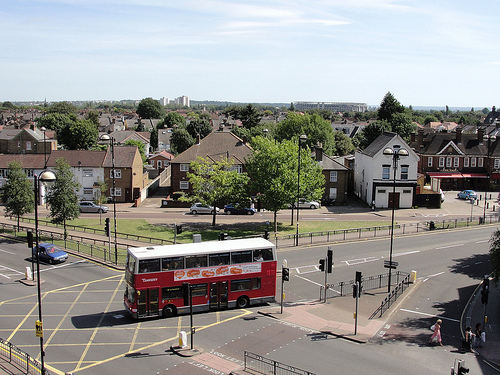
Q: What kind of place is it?
A: It is a street.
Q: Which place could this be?
A: It is a street.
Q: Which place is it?
A: It is a street.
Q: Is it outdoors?
A: Yes, it is outdoors.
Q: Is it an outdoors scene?
A: Yes, it is outdoors.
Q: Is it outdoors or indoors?
A: It is outdoors.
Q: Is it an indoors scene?
A: No, it is outdoors.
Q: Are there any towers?
A: No, there are no towers.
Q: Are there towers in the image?
A: No, there are no towers.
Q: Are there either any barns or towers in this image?
A: No, there are no towers or barns.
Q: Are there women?
A: Yes, there is a woman.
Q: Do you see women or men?
A: Yes, there is a woman.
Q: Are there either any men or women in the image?
A: Yes, there is a woman.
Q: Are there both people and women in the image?
A: Yes, there are both a woman and people.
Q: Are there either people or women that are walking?
A: Yes, the woman is walking.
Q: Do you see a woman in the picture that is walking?
A: Yes, there is a woman that is walking.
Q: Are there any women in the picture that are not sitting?
A: Yes, there is a woman that is walking.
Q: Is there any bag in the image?
A: No, there are no bags.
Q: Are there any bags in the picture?
A: No, there are no bags.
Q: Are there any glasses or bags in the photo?
A: No, there are no bags or glasses.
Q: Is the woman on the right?
A: Yes, the woman is on the right of the image.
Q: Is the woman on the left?
A: No, the woman is on the right of the image.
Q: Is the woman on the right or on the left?
A: The woman is on the right of the image.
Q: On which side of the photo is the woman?
A: The woman is on the right of the image.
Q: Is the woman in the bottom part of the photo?
A: Yes, the woman is in the bottom of the image.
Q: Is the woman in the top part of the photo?
A: No, the woman is in the bottom of the image.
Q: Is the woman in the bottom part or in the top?
A: The woman is in the bottom of the image.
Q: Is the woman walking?
A: Yes, the woman is walking.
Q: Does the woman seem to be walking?
A: Yes, the woman is walking.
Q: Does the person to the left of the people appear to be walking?
A: Yes, the woman is walking.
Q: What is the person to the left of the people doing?
A: The woman is walking.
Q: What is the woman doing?
A: The woman is walking.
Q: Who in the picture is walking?
A: The woman is walking.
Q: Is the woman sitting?
A: No, the woman is walking.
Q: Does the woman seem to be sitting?
A: No, the woman is walking.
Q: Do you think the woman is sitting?
A: No, the woman is walking.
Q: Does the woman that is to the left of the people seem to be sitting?
A: No, the woman is walking.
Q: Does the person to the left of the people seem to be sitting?
A: No, the woman is walking.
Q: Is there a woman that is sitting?
A: No, there is a woman but she is walking.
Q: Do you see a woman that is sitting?
A: No, there is a woman but she is walking.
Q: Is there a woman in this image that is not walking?
A: No, there is a woman but she is walking.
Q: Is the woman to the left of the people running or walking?
A: The woman is walking.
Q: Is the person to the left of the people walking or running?
A: The woman is walking.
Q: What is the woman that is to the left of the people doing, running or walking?
A: The woman is walking.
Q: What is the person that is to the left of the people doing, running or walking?
A: The woman is walking.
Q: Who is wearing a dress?
A: The woman is wearing a dress.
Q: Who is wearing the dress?
A: The woman is wearing a dress.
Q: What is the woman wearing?
A: The woman is wearing a dress.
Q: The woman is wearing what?
A: The woman is wearing a dress.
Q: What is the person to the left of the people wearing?
A: The woman is wearing a dress.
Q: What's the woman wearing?
A: The woman is wearing a dress.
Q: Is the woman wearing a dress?
A: Yes, the woman is wearing a dress.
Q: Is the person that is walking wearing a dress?
A: Yes, the woman is wearing a dress.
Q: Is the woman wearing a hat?
A: No, the woman is wearing a dress.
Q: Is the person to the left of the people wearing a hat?
A: No, the woman is wearing a dress.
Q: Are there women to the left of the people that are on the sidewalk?
A: Yes, there is a woman to the left of the people.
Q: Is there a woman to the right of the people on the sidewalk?
A: No, the woman is to the left of the people.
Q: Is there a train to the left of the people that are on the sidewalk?
A: No, there is a woman to the left of the people.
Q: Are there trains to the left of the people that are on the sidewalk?
A: No, there is a woman to the left of the people.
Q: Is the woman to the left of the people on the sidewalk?
A: Yes, the woman is to the left of the people.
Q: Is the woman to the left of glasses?
A: No, the woman is to the left of the people.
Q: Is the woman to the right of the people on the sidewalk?
A: No, the woman is to the left of the people.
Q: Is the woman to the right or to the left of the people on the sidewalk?
A: The woman is to the left of the people.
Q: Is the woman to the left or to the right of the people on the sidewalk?
A: The woman is to the left of the people.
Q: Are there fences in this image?
A: Yes, there is a fence.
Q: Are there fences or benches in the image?
A: Yes, there is a fence.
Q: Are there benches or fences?
A: Yes, there is a fence.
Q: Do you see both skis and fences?
A: No, there is a fence but no skis.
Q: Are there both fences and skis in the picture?
A: No, there is a fence but no skis.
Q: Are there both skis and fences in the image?
A: No, there is a fence but no skis.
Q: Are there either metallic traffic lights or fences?
A: Yes, there is a metal fence.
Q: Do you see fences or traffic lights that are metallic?
A: Yes, the fence is metallic.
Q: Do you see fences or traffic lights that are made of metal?
A: Yes, the fence is made of metal.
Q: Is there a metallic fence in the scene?
A: Yes, there is a metal fence.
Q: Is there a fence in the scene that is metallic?
A: Yes, there is a fence that is metallic.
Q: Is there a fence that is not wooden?
A: Yes, there is a metallic fence.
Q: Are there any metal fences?
A: Yes, there is a fence that is made of metal.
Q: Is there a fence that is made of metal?
A: Yes, there is a fence that is made of metal.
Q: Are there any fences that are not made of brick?
A: Yes, there is a fence that is made of metal.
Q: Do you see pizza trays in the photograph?
A: No, there are no pizza trays.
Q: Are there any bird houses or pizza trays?
A: No, there are no pizza trays or bird houses.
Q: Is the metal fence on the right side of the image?
A: Yes, the fence is on the right of the image.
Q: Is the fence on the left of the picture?
A: No, the fence is on the right of the image.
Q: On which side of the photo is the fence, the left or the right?
A: The fence is on the right of the image.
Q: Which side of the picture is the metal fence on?
A: The fence is on the right of the image.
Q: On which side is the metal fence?
A: The fence is on the right of the image.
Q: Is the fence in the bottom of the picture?
A: Yes, the fence is in the bottom of the image.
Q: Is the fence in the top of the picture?
A: No, the fence is in the bottom of the image.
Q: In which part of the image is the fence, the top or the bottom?
A: The fence is in the bottom of the image.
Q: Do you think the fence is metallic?
A: Yes, the fence is metallic.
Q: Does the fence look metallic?
A: Yes, the fence is metallic.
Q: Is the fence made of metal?
A: Yes, the fence is made of metal.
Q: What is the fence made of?
A: The fence is made of metal.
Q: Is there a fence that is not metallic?
A: No, there is a fence but it is metallic.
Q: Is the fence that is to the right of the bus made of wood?
A: No, the fence is made of metal.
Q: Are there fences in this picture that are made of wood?
A: No, there is a fence but it is made of metal.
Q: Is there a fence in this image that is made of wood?
A: No, there is a fence but it is made of metal.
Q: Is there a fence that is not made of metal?
A: No, there is a fence but it is made of metal.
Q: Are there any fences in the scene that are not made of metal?
A: No, there is a fence but it is made of metal.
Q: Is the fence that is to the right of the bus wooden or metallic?
A: The fence is metallic.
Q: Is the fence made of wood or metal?
A: The fence is made of metal.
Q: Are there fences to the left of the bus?
A: No, the fence is to the right of the bus.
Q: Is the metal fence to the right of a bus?
A: Yes, the fence is to the right of a bus.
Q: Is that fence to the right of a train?
A: No, the fence is to the right of a bus.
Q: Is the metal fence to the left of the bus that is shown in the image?
A: No, the fence is to the right of the bus.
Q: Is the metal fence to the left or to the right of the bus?
A: The fence is to the right of the bus.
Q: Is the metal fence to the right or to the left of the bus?
A: The fence is to the right of the bus.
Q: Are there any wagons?
A: No, there are no wagons.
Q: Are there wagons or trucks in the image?
A: No, there are no wagons or trucks.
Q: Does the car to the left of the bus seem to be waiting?
A: Yes, the car is waiting.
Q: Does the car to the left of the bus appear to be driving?
A: No, the car is waiting.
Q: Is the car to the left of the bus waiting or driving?
A: The car is waiting.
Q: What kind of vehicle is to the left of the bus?
A: The vehicle is a car.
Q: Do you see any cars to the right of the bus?
A: No, the car is to the left of the bus.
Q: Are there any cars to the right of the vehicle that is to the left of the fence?
A: No, the car is to the left of the bus.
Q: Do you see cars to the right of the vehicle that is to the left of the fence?
A: No, the car is to the left of the bus.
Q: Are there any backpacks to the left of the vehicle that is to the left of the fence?
A: No, there is a car to the left of the bus.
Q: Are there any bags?
A: No, there are no bags.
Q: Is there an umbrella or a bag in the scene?
A: No, there are no bags or umbrellas.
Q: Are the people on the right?
A: Yes, the people are on the right of the image.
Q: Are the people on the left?
A: No, the people are on the right of the image.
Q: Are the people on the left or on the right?
A: The people are on the right of the image.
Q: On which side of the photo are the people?
A: The people are on the right of the image.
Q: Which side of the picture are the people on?
A: The people are on the right of the image.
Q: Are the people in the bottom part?
A: Yes, the people are in the bottom of the image.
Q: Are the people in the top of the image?
A: No, the people are in the bottom of the image.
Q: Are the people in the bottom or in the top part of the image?
A: The people are in the bottom of the image.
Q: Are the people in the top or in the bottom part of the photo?
A: The people are in the bottom of the image.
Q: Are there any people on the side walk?
A: Yes, there are people on the side walk.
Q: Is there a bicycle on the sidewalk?
A: No, there are people on the sidewalk.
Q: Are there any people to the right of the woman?
A: Yes, there are people to the right of the woman.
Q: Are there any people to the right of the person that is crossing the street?
A: Yes, there are people to the right of the woman.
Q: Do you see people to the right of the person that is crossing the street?
A: Yes, there are people to the right of the woman.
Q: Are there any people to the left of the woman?
A: No, the people are to the right of the woman.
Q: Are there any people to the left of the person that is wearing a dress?
A: No, the people are to the right of the woman.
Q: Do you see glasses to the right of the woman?
A: No, there are people to the right of the woman.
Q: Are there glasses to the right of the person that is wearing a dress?
A: No, there are people to the right of the woman.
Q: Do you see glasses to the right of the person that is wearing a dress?
A: No, there are people to the right of the woman.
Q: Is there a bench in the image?
A: No, there are no benches.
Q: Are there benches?
A: No, there are no benches.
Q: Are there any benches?
A: No, there are no benches.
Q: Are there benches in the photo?
A: No, there are no benches.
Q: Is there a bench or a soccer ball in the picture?
A: No, there are no benches or soccer balls.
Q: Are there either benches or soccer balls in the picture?
A: No, there are no benches or soccer balls.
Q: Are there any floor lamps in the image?
A: No, there are no floor lamps.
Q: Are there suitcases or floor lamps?
A: No, there are no floor lamps or suitcases.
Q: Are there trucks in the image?
A: No, there are no trucks.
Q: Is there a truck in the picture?
A: No, there are no trucks.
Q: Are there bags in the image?
A: No, there are no bags.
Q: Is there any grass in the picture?
A: Yes, there is grass.